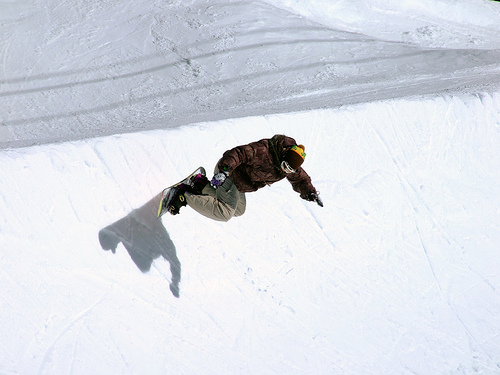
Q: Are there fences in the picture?
A: No, there are no fences.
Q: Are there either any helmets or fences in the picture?
A: No, there are no fences or helmets.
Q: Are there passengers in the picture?
A: No, there are no passengers.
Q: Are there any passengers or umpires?
A: No, there are no passengers or umpires.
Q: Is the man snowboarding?
A: Yes, the man is snowboarding.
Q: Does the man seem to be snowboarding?
A: Yes, the man is snowboarding.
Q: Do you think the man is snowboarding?
A: Yes, the man is snowboarding.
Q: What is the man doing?
A: The man is snowboarding.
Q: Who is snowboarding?
A: The man is snowboarding.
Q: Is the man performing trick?
A: No, the man is snowboarding.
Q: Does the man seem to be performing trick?
A: No, the man is snowboarding.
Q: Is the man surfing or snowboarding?
A: The man is snowboarding.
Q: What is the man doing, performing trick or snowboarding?
A: The man is snowboarding.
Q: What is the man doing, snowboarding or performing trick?
A: The man is snowboarding.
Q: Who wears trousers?
A: The man wears trousers.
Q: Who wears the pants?
A: The man wears trousers.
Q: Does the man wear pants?
A: Yes, the man wears pants.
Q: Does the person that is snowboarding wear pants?
A: Yes, the man wears pants.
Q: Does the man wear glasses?
A: No, the man wears pants.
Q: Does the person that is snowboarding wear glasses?
A: No, the man wears pants.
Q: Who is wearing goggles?
A: The man is wearing goggles.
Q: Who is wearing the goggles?
A: The man is wearing goggles.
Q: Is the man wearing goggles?
A: Yes, the man is wearing goggles.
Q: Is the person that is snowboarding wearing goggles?
A: Yes, the man is wearing goggles.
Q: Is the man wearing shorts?
A: No, the man is wearing goggles.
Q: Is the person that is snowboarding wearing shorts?
A: No, the man is wearing goggles.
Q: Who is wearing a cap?
A: The man is wearing a cap.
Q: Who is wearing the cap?
A: The man is wearing a cap.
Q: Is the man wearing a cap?
A: Yes, the man is wearing a cap.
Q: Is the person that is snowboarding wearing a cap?
A: Yes, the man is wearing a cap.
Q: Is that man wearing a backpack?
A: No, the man is wearing a cap.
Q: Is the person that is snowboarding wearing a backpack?
A: No, the man is wearing a cap.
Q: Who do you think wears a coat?
A: The man wears a coat.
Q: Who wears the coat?
A: The man wears a coat.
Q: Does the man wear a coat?
A: Yes, the man wears a coat.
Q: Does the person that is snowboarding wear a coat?
A: Yes, the man wears a coat.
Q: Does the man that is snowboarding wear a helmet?
A: No, the man wears a coat.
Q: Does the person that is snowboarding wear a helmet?
A: No, the man wears a coat.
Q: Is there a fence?
A: No, there are no fences.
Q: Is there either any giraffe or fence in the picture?
A: No, there are no fences or giraffes.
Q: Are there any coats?
A: Yes, there is a coat.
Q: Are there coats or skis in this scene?
A: Yes, there is a coat.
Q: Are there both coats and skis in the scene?
A: No, there is a coat but no skis.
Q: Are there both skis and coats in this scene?
A: No, there is a coat but no skis.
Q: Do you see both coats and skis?
A: No, there is a coat but no skis.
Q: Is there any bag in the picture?
A: No, there are no bags.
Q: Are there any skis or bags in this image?
A: No, there are no bags or skis.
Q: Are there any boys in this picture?
A: No, there are no boys.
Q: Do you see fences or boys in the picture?
A: No, there are no boys or fences.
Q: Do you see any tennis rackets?
A: No, there are no tennis rackets.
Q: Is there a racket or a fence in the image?
A: No, there are no rackets or fences.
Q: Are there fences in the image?
A: No, there are no fences.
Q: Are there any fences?
A: No, there are no fences.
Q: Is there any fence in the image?
A: No, there are no fences.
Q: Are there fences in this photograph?
A: No, there are no fences.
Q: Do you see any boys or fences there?
A: No, there are no fences or boys.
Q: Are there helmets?
A: No, there are no helmets.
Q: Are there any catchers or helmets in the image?
A: No, there are no helmets or catchers.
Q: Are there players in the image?
A: No, there are no players.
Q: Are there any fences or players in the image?
A: No, there are no players or fences.